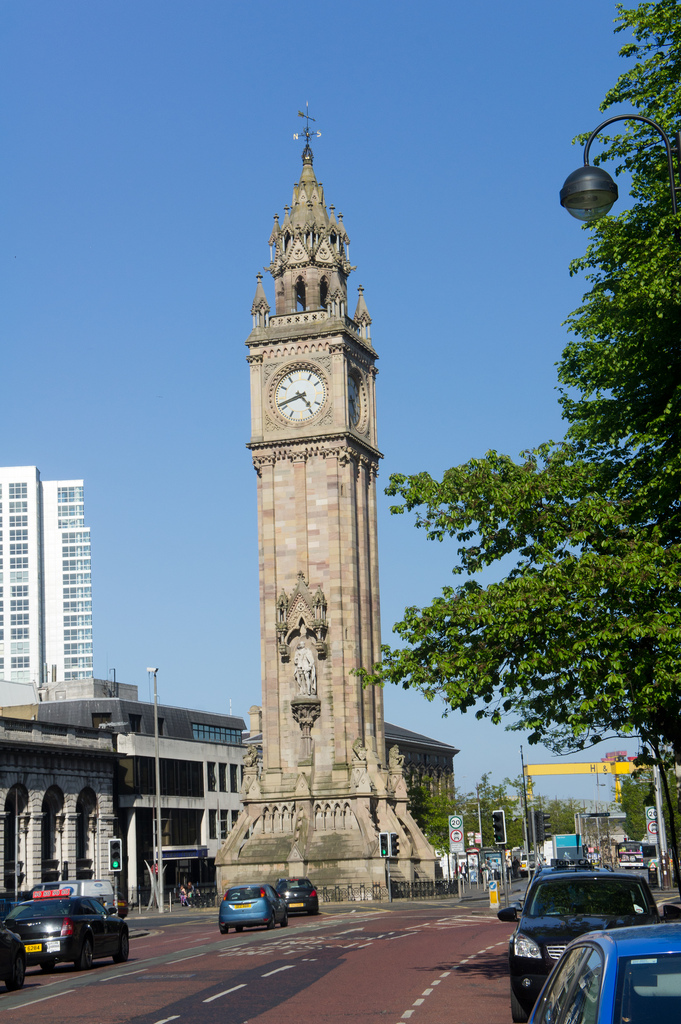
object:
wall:
[254, 756, 312, 791]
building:
[211, 97, 445, 912]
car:
[275, 876, 320, 917]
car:
[0, 917, 30, 994]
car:
[0, 887, 131, 972]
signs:
[448, 814, 465, 854]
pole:
[454, 852, 462, 899]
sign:
[520, 759, 653, 776]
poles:
[652, 763, 670, 889]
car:
[494, 857, 680, 1023]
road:
[0, 874, 629, 1023]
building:
[0, 719, 128, 925]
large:
[208, 97, 448, 901]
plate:
[23, 942, 43, 953]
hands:
[295, 389, 312, 408]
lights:
[556, 111, 679, 229]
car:
[218, 884, 289, 936]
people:
[178, 879, 187, 907]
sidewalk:
[109, 893, 219, 921]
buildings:
[0, 693, 462, 913]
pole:
[581, 110, 680, 217]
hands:
[277, 391, 306, 408]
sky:
[0, 0, 203, 320]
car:
[522, 919, 681, 1022]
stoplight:
[378, 832, 390, 858]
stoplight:
[389, 831, 400, 859]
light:
[112, 860, 119, 869]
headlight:
[513, 932, 543, 960]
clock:
[264, 358, 334, 431]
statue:
[292, 640, 318, 697]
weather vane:
[292, 99, 322, 160]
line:
[402, 938, 511, 1022]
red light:
[259, 887, 265, 895]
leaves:
[347, 567, 496, 726]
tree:
[347, 22, 680, 904]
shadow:
[406, 948, 510, 981]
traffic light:
[107, 838, 123, 872]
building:
[0, 461, 96, 704]